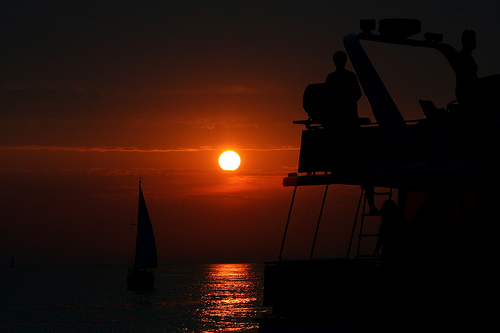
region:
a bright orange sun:
[213, 139, 246, 174]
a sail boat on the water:
[129, 182, 163, 299]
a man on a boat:
[300, 36, 384, 216]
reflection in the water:
[196, 261, 262, 326]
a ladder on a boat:
[351, 166, 398, 269]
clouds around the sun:
[4, 2, 300, 181]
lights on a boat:
[345, 11, 472, 47]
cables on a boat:
[272, 186, 307, 256]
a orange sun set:
[11, 21, 270, 184]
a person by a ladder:
[356, 196, 410, 286]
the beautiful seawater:
[19, 263, 371, 330]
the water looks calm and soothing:
[15, 266, 310, 331]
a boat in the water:
[126, 180, 161, 301]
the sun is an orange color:
[206, 143, 246, 173]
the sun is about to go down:
[217, 142, 247, 178]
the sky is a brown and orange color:
[12, 108, 492, 250]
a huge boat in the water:
[257, 46, 498, 321]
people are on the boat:
[326, 35, 494, 267]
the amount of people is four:
[322, 28, 492, 288]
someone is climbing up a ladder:
[358, 185, 381, 230]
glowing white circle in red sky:
[182, 132, 268, 188]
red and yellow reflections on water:
[200, 257, 260, 327]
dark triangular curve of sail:
[130, 161, 161, 271]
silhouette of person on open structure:
[282, 10, 483, 275]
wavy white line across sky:
[5, 135, 295, 157]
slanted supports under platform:
[270, 172, 365, 262]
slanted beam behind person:
[325, 10, 402, 140]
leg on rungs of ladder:
[351, 180, 391, 260]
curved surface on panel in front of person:
[285, 70, 330, 120]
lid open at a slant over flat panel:
[406, 87, 444, 127]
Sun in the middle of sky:
[219, 150, 240, 170]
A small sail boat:
[125, 167, 158, 297]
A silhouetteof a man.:
[323, 46, 363, 132]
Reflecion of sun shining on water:
[196, 263, 264, 330]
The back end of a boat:
[254, 16, 499, 331]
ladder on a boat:
[356, 180, 394, 260]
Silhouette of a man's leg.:
[363, 185, 383, 217]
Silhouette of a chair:
[418, 98, 453, 120]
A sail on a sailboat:
[130, 171, 160, 271]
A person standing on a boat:
[452, 26, 479, 105]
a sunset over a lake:
[22, 30, 484, 272]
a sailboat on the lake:
[94, 159, 194, 315]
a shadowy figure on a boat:
[297, 45, 372, 132]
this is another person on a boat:
[433, 17, 493, 104]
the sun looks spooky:
[189, 124, 259, 179]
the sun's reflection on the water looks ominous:
[192, 145, 272, 329]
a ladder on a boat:
[349, 180, 397, 266]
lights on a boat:
[339, 13, 445, 49]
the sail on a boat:
[118, 174, 180, 270]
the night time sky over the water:
[18, 9, 328, 246]